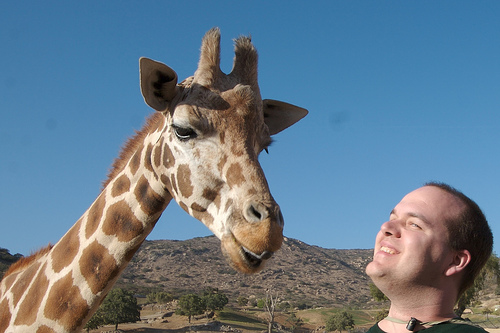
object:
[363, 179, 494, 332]
man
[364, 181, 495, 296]
head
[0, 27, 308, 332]
giraffe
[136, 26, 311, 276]
head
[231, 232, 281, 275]
mouth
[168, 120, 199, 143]
eye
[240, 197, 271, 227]
nostril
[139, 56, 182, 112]
ear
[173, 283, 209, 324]
tree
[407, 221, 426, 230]
eye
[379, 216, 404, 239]
nose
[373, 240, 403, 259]
mouth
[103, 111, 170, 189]
mane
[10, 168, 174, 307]
neck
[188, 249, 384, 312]
hill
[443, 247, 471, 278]
ear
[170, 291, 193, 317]
leaves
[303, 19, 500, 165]
sky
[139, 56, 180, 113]
ears